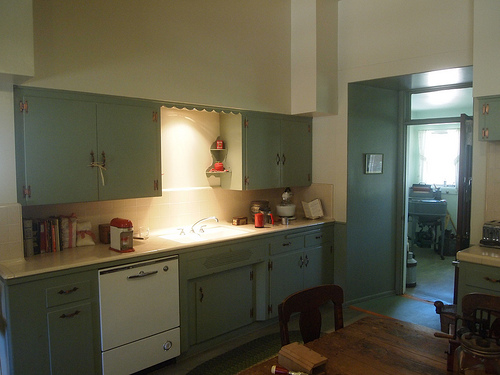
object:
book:
[301, 197, 324, 220]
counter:
[0, 214, 335, 279]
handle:
[126, 270, 159, 279]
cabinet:
[0, 265, 103, 375]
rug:
[184, 330, 330, 375]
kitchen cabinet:
[268, 224, 335, 318]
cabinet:
[180, 234, 271, 353]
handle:
[90, 150, 106, 168]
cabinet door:
[19, 95, 100, 206]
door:
[245, 116, 313, 191]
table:
[232, 313, 450, 375]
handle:
[58, 287, 80, 296]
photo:
[364, 153, 385, 175]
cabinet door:
[195, 264, 258, 345]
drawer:
[269, 226, 338, 320]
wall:
[345, 84, 398, 303]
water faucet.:
[176, 216, 220, 238]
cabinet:
[13, 85, 163, 208]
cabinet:
[219, 110, 313, 191]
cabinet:
[98, 254, 183, 375]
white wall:
[0, 0, 500, 248]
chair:
[278, 284, 345, 347]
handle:
[89, 150, 95, 168]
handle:
[101, 150, 107, 169]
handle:
[277, 153, 281, 165]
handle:
[282, 153, 286, 165]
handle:
[199, 286, 205, 302]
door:
[281, 114, 314, 187]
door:
[245, 117, 281, 192]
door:
[97, 102, 163, 201]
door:
[195, 263, 256, 344]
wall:
[1, 0, 500, 375]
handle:
[300, 254, 305, 268]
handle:
[305, 254, 310, 267]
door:
[268, 250, 305, 320]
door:
[303, 242, 336, 290]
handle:
[276, 153, 285, 166]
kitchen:
[0, 0, 500, 375]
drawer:
[0, 270, 103, 375]